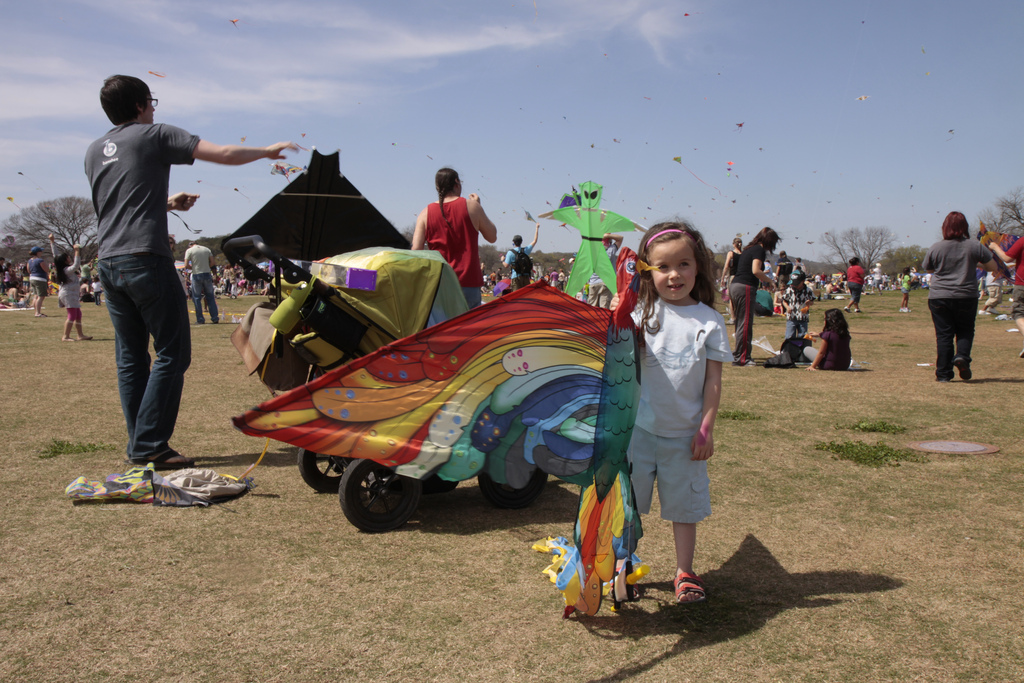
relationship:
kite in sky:
[582, 136, 595, 147] [2, 1, 999, 255]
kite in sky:
[933, 120, 949, 133] [11, 7, 992, 273]